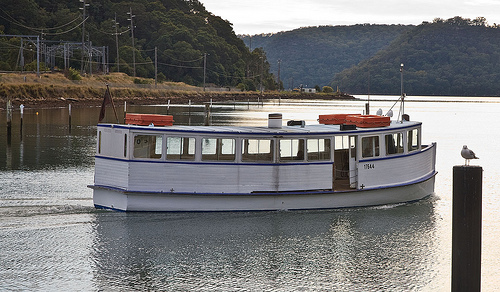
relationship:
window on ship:
[279, 135, 306, 164] [88, 107, 438, 226]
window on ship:
[179, 132, 269, 170] [62, 76, 495, 242]